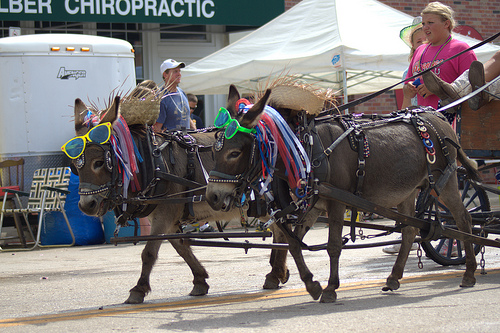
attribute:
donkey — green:
[201, 79, 483, 306]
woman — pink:
[400, 1, 481, 139]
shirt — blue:
[156, 84, 195, 130]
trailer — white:
[0, 28, 139, 165]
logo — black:
[52, 63, 90, 84]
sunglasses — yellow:
[45, 119, 125, 161]